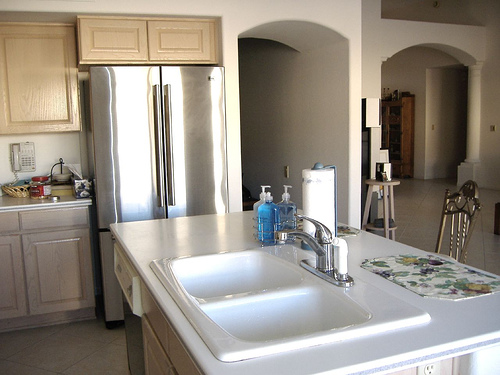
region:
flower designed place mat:
[360, 248, 497, 300]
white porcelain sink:
[150, 236, 431, 366]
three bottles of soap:
[250, 177, 297, 242]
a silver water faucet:
[275, 210, 355, 285]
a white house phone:
[5, 136, 35, 176]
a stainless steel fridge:
[80, 60, 227, 327]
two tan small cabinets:
[70, 10, 225, 66]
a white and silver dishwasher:
[108, 233, 148, 373]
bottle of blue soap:
[255, 188, 281, 243]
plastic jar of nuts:
[27, 174, 54, 201]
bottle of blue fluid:
[254, 189, 279, 244]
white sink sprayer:
[327, 233, 349, 285]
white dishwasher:
[108, 238, 146, 372]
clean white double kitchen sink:
[149, 235, 436, 361]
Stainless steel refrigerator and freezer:
[86, 63, 238, 214]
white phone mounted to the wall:
[7, 139, 36, 175]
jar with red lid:
[27, 174, 55, 202]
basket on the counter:
[2, 178, 31, 200]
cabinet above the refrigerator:
[75, 13, 225, 67]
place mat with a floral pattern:
[358, 248, 498, 312]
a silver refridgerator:
[94, 71, 258, 335]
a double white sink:
[157, 223, 419, 366]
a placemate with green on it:
[369, 242, 499, 324]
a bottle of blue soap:
[258, 194, 294, 242]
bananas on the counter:
[4, 175, 36, 202]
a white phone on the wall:
[8, 138, 48, 180]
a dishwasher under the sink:
[101, 243, 153, 374]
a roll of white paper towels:
[291, 147, 371, 267]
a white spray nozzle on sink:
[319, 225, 367, 292]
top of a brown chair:
[426, 176, 491, 268]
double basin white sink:
[155, 230, 433, 368]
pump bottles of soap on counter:
[249, 184, 299, 241]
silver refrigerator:
[89, 69, 234, 315]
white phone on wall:
[6, 137, 36, 176]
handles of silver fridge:
[150, 74, 185, 210]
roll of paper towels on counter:
[299, 162, 337, 243]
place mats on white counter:
[332, 219, 492, 309]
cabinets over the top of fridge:
[79, 22, 211, 69]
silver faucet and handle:
[272, 209, 337, 276]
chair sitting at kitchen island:
[413, 184, 478, 260]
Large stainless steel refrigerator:
[88, 65, 229, 330]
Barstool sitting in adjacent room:
[360, 177, 400, 238]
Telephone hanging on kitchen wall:
[10, 140, 37, 178]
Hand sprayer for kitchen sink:
[330, 236, 350, 281]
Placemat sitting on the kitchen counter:
[357, 253, 499, 302]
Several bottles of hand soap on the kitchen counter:
[252, 183, 298, 245]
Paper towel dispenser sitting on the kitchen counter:
[298, 162, 335, 252]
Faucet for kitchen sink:
[275, 213, 353, 290]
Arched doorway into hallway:
[236, 19, 353, 229]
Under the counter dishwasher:
[109, 239, 145, 374]